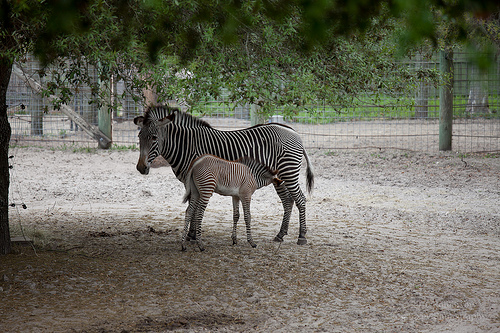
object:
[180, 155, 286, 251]
calf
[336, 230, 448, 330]
ground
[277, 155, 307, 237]
legs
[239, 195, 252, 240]
legs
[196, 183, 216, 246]
legs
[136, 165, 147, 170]
zebra nose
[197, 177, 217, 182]
stripes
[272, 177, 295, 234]
legs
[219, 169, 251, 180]
skin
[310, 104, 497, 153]
fence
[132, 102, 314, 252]
zebra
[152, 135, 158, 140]
eye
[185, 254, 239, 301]
foot prints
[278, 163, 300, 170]
stripe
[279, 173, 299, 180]
stripe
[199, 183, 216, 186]
stripe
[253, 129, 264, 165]
stripe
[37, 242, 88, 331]
sand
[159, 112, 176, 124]
ear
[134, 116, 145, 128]
ear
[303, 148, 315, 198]
tail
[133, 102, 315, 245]
mother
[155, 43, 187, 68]
green leaves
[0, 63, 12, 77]
bark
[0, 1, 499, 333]
photo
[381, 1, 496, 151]
tree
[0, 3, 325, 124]
tree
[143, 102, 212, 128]
hair